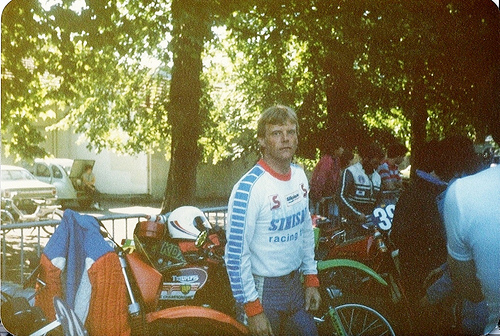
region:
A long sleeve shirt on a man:
[220, 159, 322, 315]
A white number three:
[372, 201, 393, 239]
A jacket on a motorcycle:
[33, 209, 132, 335]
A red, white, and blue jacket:
[35, 207, 135, 334]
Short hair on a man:
[257, 108, 299, 135]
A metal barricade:
[0, 186, 341, 295]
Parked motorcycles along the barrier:
[0, 204, 414, 335]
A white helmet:
[164, 198, 216, 247]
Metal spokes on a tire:
[319, 300, 389, 335]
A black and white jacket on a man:
[335, 161, 380, 223]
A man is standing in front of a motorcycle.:
[218, 100, 338, 335]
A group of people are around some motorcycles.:
[300, 65, 495, 330]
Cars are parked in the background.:
[0, 146, 105, 226]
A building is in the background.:
[36, 68, 262, 204]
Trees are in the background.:
[2, 1, 499, 217]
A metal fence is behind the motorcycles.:
[0, 195, 354, 307]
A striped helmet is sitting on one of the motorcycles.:
[161, 201, 221, 249]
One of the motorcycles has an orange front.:
[7, 233, 258, 333]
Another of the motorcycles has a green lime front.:
[305, 225, 412, 335]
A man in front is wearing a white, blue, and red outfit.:
[220, 151, 325, 335]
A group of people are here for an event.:
[197, 76, 497, 327]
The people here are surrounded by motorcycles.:
[5, 86, 466, 329]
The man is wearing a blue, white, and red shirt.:
[230, 100, 330, 330]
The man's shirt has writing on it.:
[225, 100, 330, 332]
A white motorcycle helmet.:
[160, 195, 210, 245]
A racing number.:
[370, 197, 410, 239]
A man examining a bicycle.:
[337, 140, 379, 230]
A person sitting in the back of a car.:
[30, 150, 115, 210]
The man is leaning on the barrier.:
[305, 132, 345, 212]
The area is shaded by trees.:
[10, 6, 492, 207]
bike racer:
[160, 91, 358, 333]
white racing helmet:
[157, 195, 217, 254]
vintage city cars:
[2, 137, 118, 214]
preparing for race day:
[43, 102, 445, 334]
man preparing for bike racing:
[107, 88, 416, 330]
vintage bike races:
[87, 127, 496, 316]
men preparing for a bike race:
[311, 116, 491, 314]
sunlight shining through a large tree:
[27, 3, 234, 163]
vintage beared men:
[320, 123, 410, 235]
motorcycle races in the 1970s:
[44, 94, 398, 332]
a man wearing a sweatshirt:
[208, 109, 333, 330]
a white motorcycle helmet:
[157, 199, 215, 245]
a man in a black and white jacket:
[328, 144, 388, 221]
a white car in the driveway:
[30, 150, 81, 210]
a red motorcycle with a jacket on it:
[36, 240, 268, 334]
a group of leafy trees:
[336, 16, 491, 121]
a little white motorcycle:
[6, 191, 67, 236]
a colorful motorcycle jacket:
[41, 214, 139, 333]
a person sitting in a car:
[71, 154, 111, 205]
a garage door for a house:
[66, 111, 150, 208]